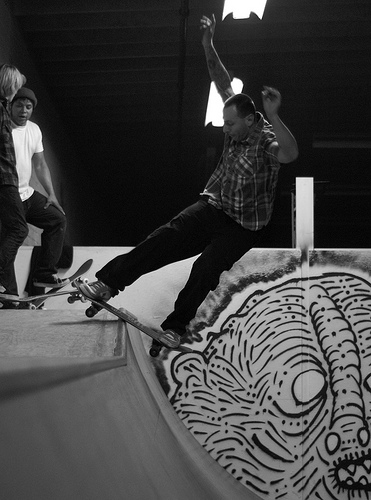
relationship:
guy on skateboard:
[81, 11, 302, 350] [67, 276, 194, 358]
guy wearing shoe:
[81, 11, 302, 350] [158, 327, 181, 347]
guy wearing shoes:
[81, 11, 302, 350] [0, 274, 67, 307]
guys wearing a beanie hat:
[10, 82, 73, 305] [12, 86, 35, 99]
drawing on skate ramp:
[169, 270, 369, 498] [0, 310, 278, 498]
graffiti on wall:
[266, 280, 351, 368] [10, 247, 369, 497]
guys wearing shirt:
[10, 82, 73, 305] [10, 112, 47, 205]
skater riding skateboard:
[64, 7, 295, 357] [70, 278, 190, 362]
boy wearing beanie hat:
[11, 87, 74, 290] [12, 86, 35, 99]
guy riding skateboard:
[81, 11, 302, 350] [74, 286, 192, 371]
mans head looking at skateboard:
[220, 92, 258, 142] [67, 274, 183, 358]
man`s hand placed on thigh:
[43, 195, 64, 219] [25, 191, 65, 229]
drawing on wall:
[215, 291, 369, 445] [168, 257, 365, 497]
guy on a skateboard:
[81, 11, 302, 350] [67, 276, 194, 358]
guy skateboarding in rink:
[81, 11, 302, 350] [0, 246, 370, 498]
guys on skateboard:
[2, 64, 73, 305] [1, 257, 93, 310]